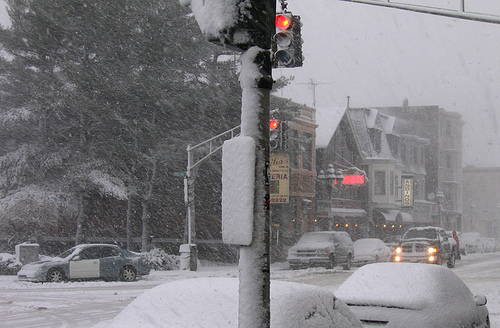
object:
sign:
[221, 135, 255, 244]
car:
[17, 226, 499, 328]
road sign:
[172, 171, 187, 176]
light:
[275, 14, 291, 30]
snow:
[0, 260, 489, 328]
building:
[268, 93, 463, 263]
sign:
[270, 153, 291, 203]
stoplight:
[275, 10, 306, 69]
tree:
[0, 0, 307, 255]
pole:
[193, 0, 301, 328]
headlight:
[394, 247, 402, 263]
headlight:
[427, 247, 436, 262]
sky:
[271, 3, 500, 168]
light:
[269, 119, 279, 129]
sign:
[334, 175, 365, 185]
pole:
[179, 144, 197, 272]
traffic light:
[270, 119, 289, 150]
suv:
[287, 231, 355, 270]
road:
[0, 239, 499, 326]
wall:
[288, 169, 316, 198]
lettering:
[271, 174, 288, 180]